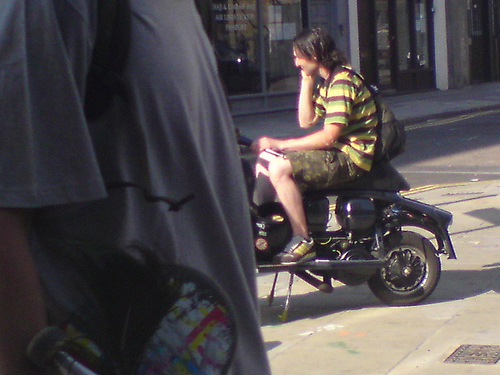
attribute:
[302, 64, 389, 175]
shirt — multi-colored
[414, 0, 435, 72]
store window — tall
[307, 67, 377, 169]
shirt — short sleeve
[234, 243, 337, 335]
kick stand — silver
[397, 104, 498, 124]
sidewalk curb — long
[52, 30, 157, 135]
strap — black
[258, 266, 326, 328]
kickstands — pair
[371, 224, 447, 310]
tire — small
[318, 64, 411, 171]
backpack — black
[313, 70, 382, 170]
shirt — striped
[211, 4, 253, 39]
window — glass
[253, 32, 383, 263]
male — white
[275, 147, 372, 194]
shorts — camo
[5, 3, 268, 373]
tee shirt — grey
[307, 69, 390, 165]
shirt — striped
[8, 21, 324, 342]
shirt — gray